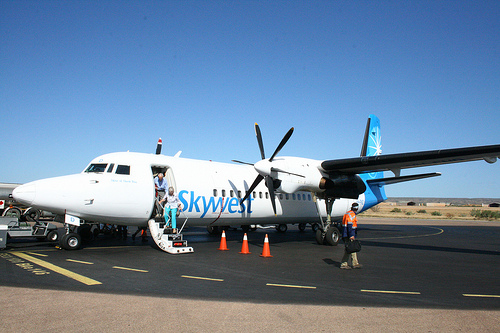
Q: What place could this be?
A: It is a runway.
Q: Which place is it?
A: It is a runway.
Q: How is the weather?
A: It is cloudless.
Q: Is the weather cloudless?
A: Yes, it is cloudless.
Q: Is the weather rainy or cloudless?
A: It is cloudless.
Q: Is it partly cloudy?
A: No, it is cloudless.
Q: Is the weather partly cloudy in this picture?
A: No, it is cloudless.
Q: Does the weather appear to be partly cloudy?
A: No, it is cloudless.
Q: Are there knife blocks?
A: No, there are no knife blocks.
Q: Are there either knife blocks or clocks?
A: No, there are no knife blocks or clocks.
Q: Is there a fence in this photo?
A: No, there are no fences.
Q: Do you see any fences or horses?
A: No, there are no fences or horses.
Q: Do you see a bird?
A: No, there are no birds.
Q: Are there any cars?
A: No, there are no cars.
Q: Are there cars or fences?
A: No, there are no cars or fences.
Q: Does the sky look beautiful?
A: Yes, the sky is beautiful.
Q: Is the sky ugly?
A: No, the sky is beautiful.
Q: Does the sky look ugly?
A: No, the sky is beautiful.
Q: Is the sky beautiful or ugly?
A: The sky is beautiful.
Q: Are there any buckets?
A: No, there are no buckets.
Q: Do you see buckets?
A: No, there are no buckets.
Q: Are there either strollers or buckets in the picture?
A: No, there are no buckets or strollers.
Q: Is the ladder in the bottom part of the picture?
A: Yes, the ladder is in the bottom of the image.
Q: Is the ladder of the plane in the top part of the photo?
A: No, the ladder is in the bottom of the image.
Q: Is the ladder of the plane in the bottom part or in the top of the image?
A: The ladder is in the bottom of the image.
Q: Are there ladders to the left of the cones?
A: Yes, there is a ladder to the left of the cones.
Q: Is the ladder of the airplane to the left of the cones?
A: Yes, the ladder is to the left of the cones.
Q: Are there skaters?
A: No, there are no skaters.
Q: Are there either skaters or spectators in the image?
A: No, there are no skaters or spectators.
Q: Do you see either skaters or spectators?
A: No, there are no skaters or spectators.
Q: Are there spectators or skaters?
A: No, there are no skaters or spectators.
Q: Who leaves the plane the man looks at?
A: The passengers leave the airplane.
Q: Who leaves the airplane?
A: The passengers leave the airplane.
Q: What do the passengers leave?
A: The passengers leave the airplane.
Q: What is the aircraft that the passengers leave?
A: The aircraft is an airplane.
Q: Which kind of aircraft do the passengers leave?
A: The passengers leave the plane.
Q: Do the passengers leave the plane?
A: Yes, the passengers leave the plane.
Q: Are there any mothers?
A: No, there are no mothers.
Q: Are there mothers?
A: No, there are no mothers.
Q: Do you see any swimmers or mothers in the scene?
A: No, there are no mothers or swimmers.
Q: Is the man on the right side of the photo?
A: Yes, the man is on the right of the image.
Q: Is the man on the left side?
A: No, the man is on the right of the image.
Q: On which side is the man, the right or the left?
A: The man is on the right of the image.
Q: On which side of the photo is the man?
A: The man is on the right of the image.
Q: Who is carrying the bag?
A: The man is carrying the bag.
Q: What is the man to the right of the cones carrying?
A: The man is carrying a bag.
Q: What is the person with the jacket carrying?
A: The man is carrying a bag.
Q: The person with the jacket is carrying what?
A: The man is carrying a bag.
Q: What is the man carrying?
A: The man is carrying a bag.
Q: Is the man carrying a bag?
A: Yes, the man is carrying a bag.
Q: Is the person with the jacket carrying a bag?
A: Yes, the man is carrying a bag.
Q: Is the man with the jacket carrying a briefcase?
A: No, the man is carrying a bag.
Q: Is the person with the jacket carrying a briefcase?
A: No, the man is carrying a bag.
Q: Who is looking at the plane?
A: The man is looking at the plane.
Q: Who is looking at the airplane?
A: The man is looking at the plane.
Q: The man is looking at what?
A: The man is looking at the plane.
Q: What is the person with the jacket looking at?
A: The man is looking at the plane.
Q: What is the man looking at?
A: The man is looking at the plane.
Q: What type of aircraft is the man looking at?
A: The man is looking at the airplane.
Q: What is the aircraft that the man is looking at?
A: The aircraft is an airplane.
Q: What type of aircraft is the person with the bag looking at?
A: The man is looking at the airplane.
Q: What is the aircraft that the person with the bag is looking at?
A: The aircraft is an airplane.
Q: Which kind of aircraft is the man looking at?
A: The man is looking at the airplane.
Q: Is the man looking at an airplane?
A: Yes, the man is looking at an airplane.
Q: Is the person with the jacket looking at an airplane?
A: Yes, the man is looking at an airplane.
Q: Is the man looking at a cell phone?
A: No, the man is looking at an airplane.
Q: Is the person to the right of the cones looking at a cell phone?
A: No, the man is looking at an airplane.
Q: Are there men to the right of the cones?
A: Yes, there is a man to the right of the cones.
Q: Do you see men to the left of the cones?
A: No, the man is to the right of the cones.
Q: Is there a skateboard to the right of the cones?
A: No, there is a man to the right of the cones.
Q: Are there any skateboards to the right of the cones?
A: No, there is a man to the right of the cones.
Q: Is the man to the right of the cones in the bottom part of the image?
A: Yes, the man is to the right of the cones.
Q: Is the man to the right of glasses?
A: No, the man is to the right of the cones.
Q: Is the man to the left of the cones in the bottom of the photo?
A: No, the man is to the right of the cones.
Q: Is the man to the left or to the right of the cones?
A: The man is to the right of the cones.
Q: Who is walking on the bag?
A: The man is walking on the bag.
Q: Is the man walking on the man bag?
A: Yes, the man is walking on the bag.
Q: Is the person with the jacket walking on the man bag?
A: Yes, the man is walking on the bag.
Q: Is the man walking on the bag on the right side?
A: Yes, the man is walking on the bag.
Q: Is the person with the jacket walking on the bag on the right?
A: Yes, the man is walking on the bag.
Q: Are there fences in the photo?
A: No, there are no fences.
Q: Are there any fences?
A: No, there are no fences.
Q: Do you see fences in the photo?
A: No, there are no fences.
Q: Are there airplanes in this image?
A: Yes, there is an airplane.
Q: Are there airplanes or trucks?
A: Yes, there is an airplane.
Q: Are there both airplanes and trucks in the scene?
A: No, there is an airplane but no trucks.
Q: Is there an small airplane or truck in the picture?
A: Yes, there is a small airplane.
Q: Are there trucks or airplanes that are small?
A: Yes, the airplane is small.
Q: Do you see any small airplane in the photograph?
A: Yes, there is a small airplane.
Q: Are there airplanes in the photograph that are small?
A: Yes, there is an airplane that is small.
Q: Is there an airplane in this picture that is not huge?
A: Yes, there is a small airplane.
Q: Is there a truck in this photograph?
A: No, there are no trucks.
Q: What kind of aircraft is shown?
A: The aircraft is an airplane.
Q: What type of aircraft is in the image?
A: The aircraft is an airplane.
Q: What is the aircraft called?
A: The aircraft is an airplane.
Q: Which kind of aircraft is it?
A: The aircraft is an airplane.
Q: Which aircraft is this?
A: This is an airplane.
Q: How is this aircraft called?
A: This is an airplane.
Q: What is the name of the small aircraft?
A: The aircraft is an airplane.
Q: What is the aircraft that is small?
A: The aircraft is an airplane.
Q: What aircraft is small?
A: The aircraft is an airplane.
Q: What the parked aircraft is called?
A: The aircraft is an airplane.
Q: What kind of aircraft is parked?
A: The aircraft is an airplane.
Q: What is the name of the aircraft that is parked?
A: The aircraft is an airplane.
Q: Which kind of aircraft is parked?
A: The aircraft is an airplane.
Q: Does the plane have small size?
A: Yes, the plane is small.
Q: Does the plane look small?
A: Yes, the plane is small.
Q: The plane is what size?
A: The plane is small.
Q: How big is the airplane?
A: The airplane is small.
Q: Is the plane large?
A: No, the plane is small.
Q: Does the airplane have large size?
A: No, the airplane is small.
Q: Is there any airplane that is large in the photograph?
A: No, there is an airplane but it is small.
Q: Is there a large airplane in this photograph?
A: No, there is an airplane but it is small.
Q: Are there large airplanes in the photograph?
A: No, there is an airplane but it is small.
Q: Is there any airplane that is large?
A: No, there is an airplane but it is small.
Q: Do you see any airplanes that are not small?
A: No, there is an airplane but it is small.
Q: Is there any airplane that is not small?
A: No, there is an airplane but it is small.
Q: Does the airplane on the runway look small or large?
A: The plane is small.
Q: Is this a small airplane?
A: Yes, this is a small airplane.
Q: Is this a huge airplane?
A: No, this is a small airplane.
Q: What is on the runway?
A: The plane is on the runway.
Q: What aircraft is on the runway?
A: The aircraft is an airplane.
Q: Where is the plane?
A: The plane is on the runway.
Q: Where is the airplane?
A: The plane is on the runway.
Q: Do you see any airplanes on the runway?
A: Yes, there is an airplane on the runway.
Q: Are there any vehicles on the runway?
A: No, there is an airplane on the runway.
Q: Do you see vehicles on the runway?
A: No, there is an airplane on the runway.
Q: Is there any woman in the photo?
A: Yes, there is a woman.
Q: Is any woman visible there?
A: Yes, there is a woman.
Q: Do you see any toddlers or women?
A: Yes, there is a woman.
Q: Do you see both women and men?
A: Yes, there are both a woman and a man.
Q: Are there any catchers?
A: No, there are no catchers.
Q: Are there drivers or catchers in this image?
A: No, there are no catchers or drivers.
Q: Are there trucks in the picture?
A: No, there are no trucks.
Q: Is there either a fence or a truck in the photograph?
A: No, there are no trucks or fences.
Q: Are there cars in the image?
A: No, there are no cars.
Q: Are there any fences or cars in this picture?
A: No, there are no cars or fences.